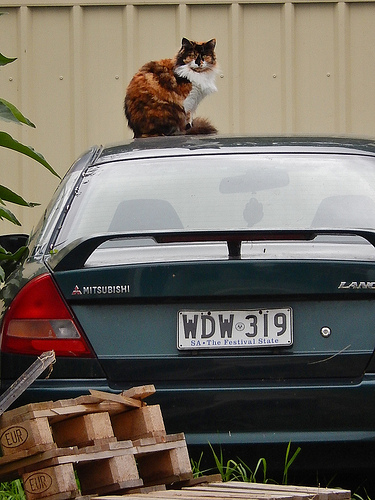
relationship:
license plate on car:
[178, 294, 300, 355] [64, 153, 367, 400]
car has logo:
[64, 153, 367, 400] [61, 272, 148, 309]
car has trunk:
[64, 153, 367, 400] [108, 249, 375, 400]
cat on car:
[134, 38, 229, 150] [64, 153, 367, 400]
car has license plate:
[64, 153, 367, 400] [178, 294, 300, 355]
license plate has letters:
[178, 294, 300, 355] [184, 313, 240, 340]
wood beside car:
[82, 389, 164, 491] [64, 153, 367, 400]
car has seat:
[64, 153, 367, 400] [125, 193, 187, 241]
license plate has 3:
[178, 294, 300, 355] [243, 310, 266, 342]